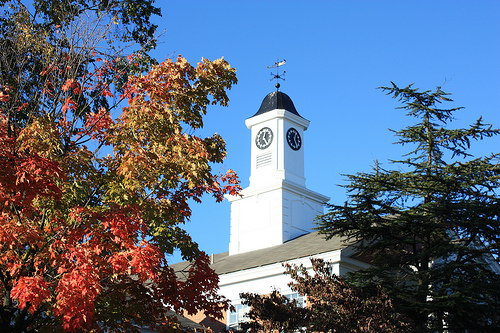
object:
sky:
[0, 1, 500, 267]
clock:
[284, 125, 304, 151]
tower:
[222, 58, 330, 255]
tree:
[310, 76, 500, 332]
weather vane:
[266, 56, 288, 91]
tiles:
[283, 219, 290, 226]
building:
[136, 58, 500, 333]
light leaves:
[16, 167, 28, 184]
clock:
[254, 126, 274, 149]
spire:
[245, 57, 307, 120]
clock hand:
[263, 136, 271, 145]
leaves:
[7, 276, 34, 308]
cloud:
[0, 0, 500, 267]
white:
[248, 216, 279, 244]